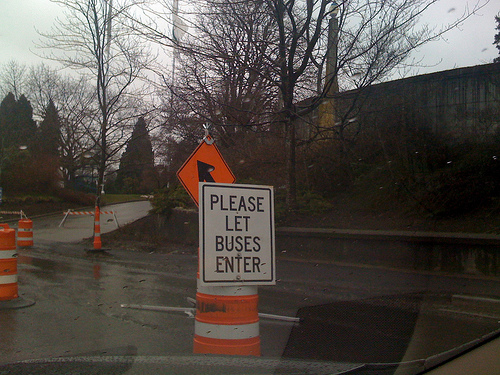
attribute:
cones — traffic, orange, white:
[18, 180, 138, 305]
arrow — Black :
[191, 156, 219, 186]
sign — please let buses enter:
[198, 183, 276, 285]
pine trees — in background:
[14, 86, 128, 210]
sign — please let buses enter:
[193, 177, 278, 287]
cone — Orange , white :
[85, 205, 110, 252]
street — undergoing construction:
[40, 228, 158, 330]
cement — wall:
[49, 199, 111, 244]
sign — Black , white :
[175, 167, 287, 304]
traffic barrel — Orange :
[192, 265, 263, 360]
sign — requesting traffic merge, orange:
[175, 132, 237, 210]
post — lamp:
[313, 0, 349, 151]